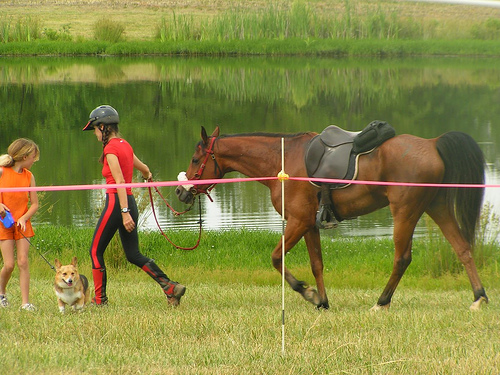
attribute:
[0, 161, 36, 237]
outfit — orange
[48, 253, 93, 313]
corgi — brown, black, adult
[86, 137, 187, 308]
outfit — red, black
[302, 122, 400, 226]
saddle — black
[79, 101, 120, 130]
helmet — black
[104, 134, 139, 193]
top — red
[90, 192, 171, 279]
pants — black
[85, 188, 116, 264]
stripe — red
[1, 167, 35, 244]
jumper — orange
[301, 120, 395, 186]
saddle — black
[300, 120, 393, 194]
harness — red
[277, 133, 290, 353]
stick — white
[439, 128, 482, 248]
thick tail — black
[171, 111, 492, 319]
horse — brown, black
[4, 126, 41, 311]
girl — walking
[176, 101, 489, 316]
brown horse — dark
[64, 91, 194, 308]
girl — leading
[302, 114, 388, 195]
horse saddle — dark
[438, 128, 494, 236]
horse tail — thick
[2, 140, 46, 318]
little girl — blonde